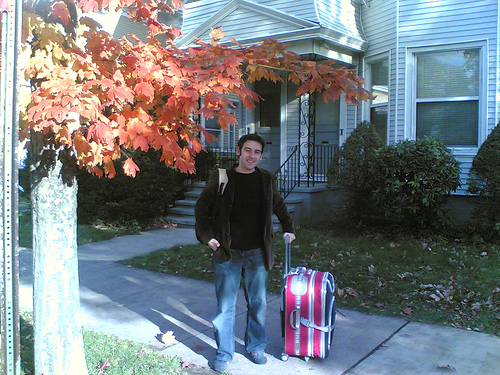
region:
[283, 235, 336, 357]
grey black and pink suitcase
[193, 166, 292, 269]
green fleece spring jacket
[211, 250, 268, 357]
medium wash denim jeans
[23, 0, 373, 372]
tree with orange leaves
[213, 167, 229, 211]
back pack on shoulder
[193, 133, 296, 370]
man standing on sidewalk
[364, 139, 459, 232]
green bush by house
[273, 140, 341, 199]
black iron railing on porch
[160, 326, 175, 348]
brown leaf on sidewalk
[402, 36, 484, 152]
glass window on building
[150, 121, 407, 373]
a guy with his suitcase on the sidewalk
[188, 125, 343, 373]
a guy standing next to his suitcase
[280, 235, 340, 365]
a pink and blue suitcase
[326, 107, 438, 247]
bushes in front of the house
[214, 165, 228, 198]
a strap of a backpack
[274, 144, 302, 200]
a railing on the stairs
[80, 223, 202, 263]
pathway leads to the house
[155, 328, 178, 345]
a leaf on the sidewalk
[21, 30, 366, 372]
a tree on the sidewalk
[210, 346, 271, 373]
shoes the guy is wearing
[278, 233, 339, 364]
red rolling bag on the sidewalk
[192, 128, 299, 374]
man standing on the sidewalk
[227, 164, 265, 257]
man's black shirt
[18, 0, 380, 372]
tree with red leaves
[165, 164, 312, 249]
stairs leading up to a house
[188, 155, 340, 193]
front stoop on a house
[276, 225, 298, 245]
hand on the handle of a suitcase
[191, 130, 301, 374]
man smiling at the camera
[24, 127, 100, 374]
trunk of a tree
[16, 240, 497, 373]
cement sidewalk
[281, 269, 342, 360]
red and white luggage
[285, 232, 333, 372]
luggge with wheels and a handle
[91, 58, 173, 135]
orange fall leaves on a tree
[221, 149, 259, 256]
black shirt on a man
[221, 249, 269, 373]
blue jeans on a man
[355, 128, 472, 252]
hedge in front of a house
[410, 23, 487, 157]
closed window on a house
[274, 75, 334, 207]
metal handrail on a porch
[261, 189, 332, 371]
man holding onto luggage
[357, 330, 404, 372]
dark line in the sidewalk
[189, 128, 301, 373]
a guy wearing jeans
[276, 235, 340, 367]
a suitcase on the sidewalk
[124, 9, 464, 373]
a guy with his suitcase in front of a house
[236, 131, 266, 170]
a facial expression of the gue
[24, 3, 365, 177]
leaves on the tree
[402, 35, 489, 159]
window of the house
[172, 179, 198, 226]
stairs of the house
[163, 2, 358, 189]
a front porch of the house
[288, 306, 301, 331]
a handle of the suitcase